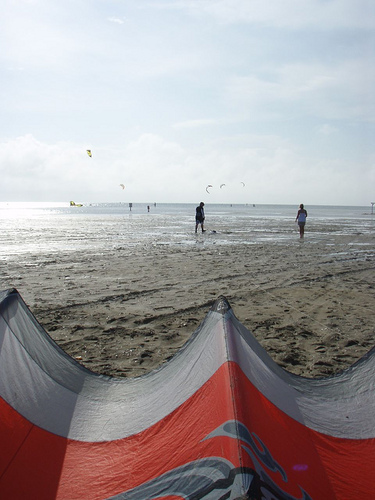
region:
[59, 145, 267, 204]
kites in the sky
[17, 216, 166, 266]
water of the ocean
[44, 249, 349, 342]
sand on the beach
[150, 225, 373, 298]
tracks in the sand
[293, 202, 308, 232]
a person standing on the beach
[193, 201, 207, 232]
a person walking along the beach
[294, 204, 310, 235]
a person wearing a white shirt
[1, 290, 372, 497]
a red and white tarp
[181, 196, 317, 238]
people standing on the beach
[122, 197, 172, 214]
signs in the water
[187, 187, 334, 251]
people walking at the beach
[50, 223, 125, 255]
the sand is wet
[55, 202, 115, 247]
the sand is wet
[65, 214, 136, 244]
the sand is wet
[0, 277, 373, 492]
part of a red and gray hang glider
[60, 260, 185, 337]
patch of sand on a beach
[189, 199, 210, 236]
man walking on a beach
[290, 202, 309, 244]
woman standing on a beach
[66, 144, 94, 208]
water sports participant with yellow equipment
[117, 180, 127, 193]
parasail in the air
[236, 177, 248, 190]
seagull flying in the distance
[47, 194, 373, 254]
people walking on a beach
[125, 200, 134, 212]
sign in the water on a beach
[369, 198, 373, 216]
buoy in the water at a beach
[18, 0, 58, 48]
white clouds in blue sky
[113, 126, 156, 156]
white clouds in blue sky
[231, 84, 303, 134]
white clouds in blue sky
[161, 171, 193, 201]
white clouds in blue sky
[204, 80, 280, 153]
white clouds in blue sky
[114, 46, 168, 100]
white clouds in blue sky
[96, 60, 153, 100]
white clouds in blue sky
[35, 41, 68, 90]
white clouds in blue sky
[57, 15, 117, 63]
white clouds in blue sky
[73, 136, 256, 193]
the kite in the air above the water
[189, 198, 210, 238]
the man walking on the beach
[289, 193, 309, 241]
the women standing in the sand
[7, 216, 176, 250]
the water on the beach sand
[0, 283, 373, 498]
the red sail on the beach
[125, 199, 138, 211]
a sign in the water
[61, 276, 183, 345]
the tire tracks on the beach sand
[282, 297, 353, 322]
the feet prints in the sand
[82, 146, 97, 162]
the yellow kite in the sunlight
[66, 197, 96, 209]
the kite surfer on the water